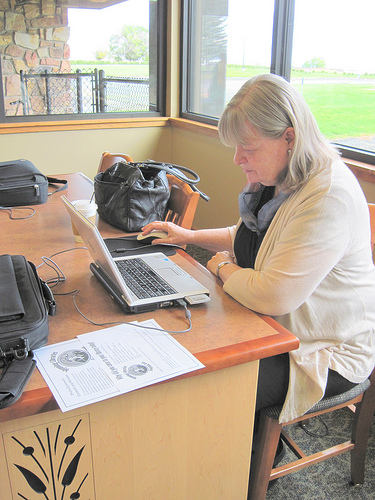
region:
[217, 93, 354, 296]
A woman seated on the chair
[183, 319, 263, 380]
A wooden table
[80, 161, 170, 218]
A bag on the table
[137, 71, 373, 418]
woman working on a laptop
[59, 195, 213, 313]
laptop is on a wooden table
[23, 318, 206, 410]
paperwork is on a wooden table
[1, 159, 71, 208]
black computer bag is on a wooden table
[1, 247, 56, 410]
black computer bag is on a wooden table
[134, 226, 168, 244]
silver mouse is on a wooden table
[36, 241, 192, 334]
cord is on a wooden table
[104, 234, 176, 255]
mouse pad is on a wooden table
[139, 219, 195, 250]
ladies hand is on a wooden table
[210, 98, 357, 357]
woman in beige sweater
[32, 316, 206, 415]
certificates on wood table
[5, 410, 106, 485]
pattern cut into desk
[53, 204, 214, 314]
silver laptop on desk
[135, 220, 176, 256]
black and grey mouse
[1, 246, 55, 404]
black laptop case on desk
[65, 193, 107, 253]
disposable coffee cup on desk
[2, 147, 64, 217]
black laptop case on desk back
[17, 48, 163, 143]
chain fencing out window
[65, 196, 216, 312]
white and black laptop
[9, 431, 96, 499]
black stencil on desk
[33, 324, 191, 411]
papers on the desk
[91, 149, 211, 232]
black handbag on the table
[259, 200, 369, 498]
chair the woman is sitting in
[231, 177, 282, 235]
gray scarf the woman is wearing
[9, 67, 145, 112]
black fencing outside the window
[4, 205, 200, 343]
black cords on the desk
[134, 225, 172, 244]
computer mouse woman's hand is on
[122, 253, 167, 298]
black keyboard on the laptop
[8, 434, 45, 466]
black pattern on desk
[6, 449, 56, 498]
black pattern on desk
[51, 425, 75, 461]
black pattern on desk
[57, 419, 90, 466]
black pattern on desk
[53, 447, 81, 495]
black pattern on desk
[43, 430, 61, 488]
black pattern on desk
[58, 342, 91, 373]
black writing on paper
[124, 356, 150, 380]
black writing on paper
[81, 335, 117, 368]
black writing on paper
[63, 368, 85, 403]
black writing on paper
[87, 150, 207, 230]
an unzipped leather handbag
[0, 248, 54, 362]
black satchel with a black folder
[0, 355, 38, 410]
padded shoulder strap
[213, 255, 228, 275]
silver watch on woman's arm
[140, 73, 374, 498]
Woman sitting on a chair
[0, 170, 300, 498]
Laptop on the table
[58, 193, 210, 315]
Laptop has black keyboard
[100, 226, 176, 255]
Mouse is on black mouse pad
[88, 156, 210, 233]
Black purse bag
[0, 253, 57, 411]
Black laptop bag